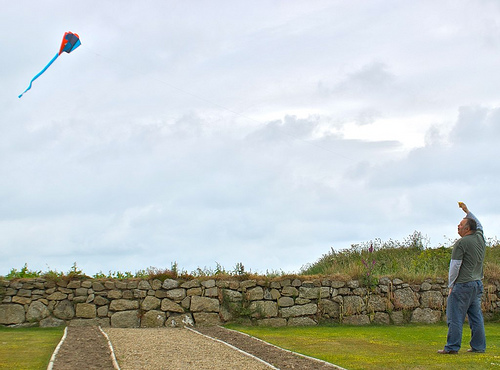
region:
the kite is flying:
[27, 19, 107, 109]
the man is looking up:
[422, 183, 497, 339]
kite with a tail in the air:
[11, 30, 86, 96]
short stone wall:
[13, 274, 427, 325]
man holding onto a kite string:
[429, 199, 491, 356]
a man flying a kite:
[14, 16, 491, 364]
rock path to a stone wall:
[54, 308, 311, 368]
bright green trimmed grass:
[247, 310, 477, 367]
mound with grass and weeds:
[300, 239, 495, 283]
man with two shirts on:
[436, 197, 488, 356]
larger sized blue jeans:
[445, 280, 488, 357]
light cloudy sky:
[40, 42, 400, 225]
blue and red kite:
[59, 31, 84, 55]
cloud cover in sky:
[3, 3, 498, 275]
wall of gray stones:
[7, 277, 495, 324]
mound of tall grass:
[308, 240, 498, 275]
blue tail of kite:
[15, 54, 61, 101]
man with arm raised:
[440, 200, 487, 353]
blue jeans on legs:
[445, 278, 487, 351]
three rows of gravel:
[44, 326, 343, 368]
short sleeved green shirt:
[450, 231, 486, 279]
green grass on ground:
[240, 322, 496, 367]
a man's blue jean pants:
[443, 278, 491, 353]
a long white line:
[183, 320, 278, 369]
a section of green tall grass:
[309, 236, 496, 280]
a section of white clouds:
[374, 111, 498, 190]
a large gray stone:
[188, 293, 220, 313]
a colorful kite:
[13, 28, 87, 105]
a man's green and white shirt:
[443, 210, 490, 290]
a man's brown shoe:
[431, 345, 460, 356]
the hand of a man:
[456, 201, 470, 209]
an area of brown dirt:
[54, 314, 108, 369]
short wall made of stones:
[8, 278, 426, 321]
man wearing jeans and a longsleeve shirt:
[440, 201, 490, 360]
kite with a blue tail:
[18, 28, 82, 98]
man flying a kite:
[443, 197, 488, 359]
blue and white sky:
[97, 31, 465, 171]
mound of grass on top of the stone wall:
[301, 235, 447, 275]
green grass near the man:
[344, 326, 427, 366]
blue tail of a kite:
[18, 51, 58, 95]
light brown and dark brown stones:
[59, 326, 309, 362]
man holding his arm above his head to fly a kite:
[438, 197, 488, 350]